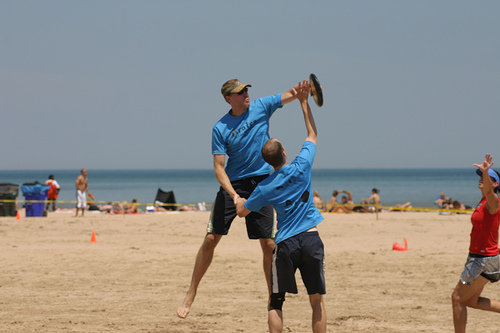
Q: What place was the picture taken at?
A: It was taken at the beach.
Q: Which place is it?
A: It is a beach.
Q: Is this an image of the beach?
A: Yes, it is showing the beach.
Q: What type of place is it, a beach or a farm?
A: It is a beach.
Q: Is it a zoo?
A: No, it is a beach.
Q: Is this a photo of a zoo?
A: No, the picture is showing a beach.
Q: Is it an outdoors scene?
A: Yes, it is outdoors.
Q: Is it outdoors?
A: Yes, it is outdoors.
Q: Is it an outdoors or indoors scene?
A: It is outdoors.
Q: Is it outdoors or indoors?
A: It is outdoors.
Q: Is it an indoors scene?
A: No, it is outdoors.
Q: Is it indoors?
A: No, it is outdoors.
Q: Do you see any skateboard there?
A: No, there are no skateboards.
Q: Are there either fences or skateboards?
A: No, there are no skateboards or fences.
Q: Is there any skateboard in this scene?
A: No, there are no skateboards.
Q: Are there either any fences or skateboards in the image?
A: No, there are no skateboards or fences.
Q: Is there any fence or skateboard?
A: No, there are no skateboards or fences.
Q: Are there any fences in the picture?
A: No, there are no fences.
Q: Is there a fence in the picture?
A: No, there are no fences.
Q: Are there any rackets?
A: No, there are no rackets.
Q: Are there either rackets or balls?
A: No, there are no rackets or balls.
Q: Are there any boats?
A: No, there are no boats.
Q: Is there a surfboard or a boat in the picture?
A: No, there are no boats or surfboards.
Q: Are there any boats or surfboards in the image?
A: No, there are no boats or surfboards.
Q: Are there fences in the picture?
A: No, there are no fences.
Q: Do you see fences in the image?
A: No, there are no fences.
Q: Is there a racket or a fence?
A: No, there are no fences or rackets.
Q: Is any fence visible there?
A: No, there are no fences.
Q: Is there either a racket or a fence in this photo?
A: No, there are no fences or rackets.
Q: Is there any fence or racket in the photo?
A: No, there are no fences or rackets.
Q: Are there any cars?
A: No, there are no cars.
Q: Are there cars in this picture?
A: No, there are no cars.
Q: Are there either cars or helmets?
A: No, there are no cars or helmets.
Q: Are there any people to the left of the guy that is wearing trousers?
A: Yes, there is a person to the left of the guy.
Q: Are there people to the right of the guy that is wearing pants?
A: No, the person is to the left of the guy.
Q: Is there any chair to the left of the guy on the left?
A: No, there is a person to the left of the guy.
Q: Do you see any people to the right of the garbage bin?
A: Yes, there is a person to the right of the garbage bin.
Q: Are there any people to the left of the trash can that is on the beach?
A: No, the person is to the right of the garbage bin.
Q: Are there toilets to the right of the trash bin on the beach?
A: No, there is a person to the right of the garbage can.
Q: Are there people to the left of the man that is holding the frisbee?
A: Yes, there is a person to the left of the man.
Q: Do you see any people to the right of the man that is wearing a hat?
A: No, the person is to the left of the man.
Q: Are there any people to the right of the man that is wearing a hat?
A: No, the person is to the left of the man.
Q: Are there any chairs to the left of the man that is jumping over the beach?
A: No, there is a person to the left of the man.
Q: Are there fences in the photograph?
A: No, there are no fences.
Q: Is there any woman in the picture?
A: Yes, there is a woman.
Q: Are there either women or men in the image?
A: Yes, there is a woman.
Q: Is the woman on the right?
A: Yes, the woman is on the right of the image.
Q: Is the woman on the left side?
A: No, the woman is on the right of the image.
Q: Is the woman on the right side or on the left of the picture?
A: The woman is on the right of the image.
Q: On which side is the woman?
A: The woman is on the right of the image.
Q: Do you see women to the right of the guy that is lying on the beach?
A: Yes, there is a woman to the right of the guy.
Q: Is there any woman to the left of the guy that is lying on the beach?
A: No, the woman is to the right of the guy.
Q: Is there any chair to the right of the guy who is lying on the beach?
A: No, there is a woman to the right of the guy.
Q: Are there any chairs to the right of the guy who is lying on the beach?
A: No, there is a woman to the right of the guy.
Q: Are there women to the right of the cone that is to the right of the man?
A: Yes, there is a woman to the right of the safety cone.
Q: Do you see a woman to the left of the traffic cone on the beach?
A: No, the woman is to the right of the traffic cone.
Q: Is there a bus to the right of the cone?
A: No, there is a woman to the right of the cone.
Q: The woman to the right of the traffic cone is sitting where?
A: The woman is sitting on the beach.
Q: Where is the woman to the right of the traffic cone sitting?
A: The woman is sitting on the beach.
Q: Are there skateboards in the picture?
A: No, there are no skateboards.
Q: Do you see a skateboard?
A: No, there are no skateboards.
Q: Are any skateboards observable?
A: No, there are no skateboards.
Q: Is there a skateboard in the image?
A: No, there are no skateboards.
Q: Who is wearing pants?
A: The guy is wearing pants.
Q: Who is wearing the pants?
A: The guy is wearing pants.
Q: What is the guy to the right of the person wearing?
A: The guy is wearing pants.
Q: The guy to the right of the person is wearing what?
A: The guy is wearing pants.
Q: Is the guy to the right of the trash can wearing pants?
A: Yes, the guy is wearing pants.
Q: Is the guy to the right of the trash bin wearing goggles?
A: No, the guy is wearing pants.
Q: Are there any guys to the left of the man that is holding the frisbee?
A: Yes, there is a guy to the left of the man.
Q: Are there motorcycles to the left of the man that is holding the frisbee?
A: No, there is a guy to the left of the man.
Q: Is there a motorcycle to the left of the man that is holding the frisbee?
A: No, there is a guy to the left of the man.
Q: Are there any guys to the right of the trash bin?
A: Yes, there is a guy to the right of the trash bin.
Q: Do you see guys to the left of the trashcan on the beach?
A: No, the guy is to the right of the garbage can.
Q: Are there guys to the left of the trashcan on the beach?
A: No, the guy is to the right of the garbage can.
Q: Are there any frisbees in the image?
A: Yes, there is a frisbee.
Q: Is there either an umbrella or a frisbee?
A: Yes, there is a frisbee.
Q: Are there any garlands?
A: No, there are no garlands.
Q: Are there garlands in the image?
A: No, there are no garlands.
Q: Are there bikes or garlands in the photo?
A: No, there are no garlands or bikes.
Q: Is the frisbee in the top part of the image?
A: Yes, the frisbee is in the top of the image.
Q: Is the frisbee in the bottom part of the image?
A: No, the frisbee is in the top of the image.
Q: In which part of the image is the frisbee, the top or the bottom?
A: The frisbee is in the top of the image.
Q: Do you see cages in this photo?
A: No, there are no cages.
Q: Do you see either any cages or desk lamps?
A: No, there are no cages or desk lamps.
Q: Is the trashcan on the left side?
A: Yes, the trashcan is on the left of the image.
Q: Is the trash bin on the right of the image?
A: No, the trash bin is on the left of the image.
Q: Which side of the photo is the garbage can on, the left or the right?
A: The garbage can is on the left of the image.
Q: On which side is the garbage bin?
A: The garbage bin is on the left of the image.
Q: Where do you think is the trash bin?
A: The trash bin is on the beach.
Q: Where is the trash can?
A: The trash bin is on the beach.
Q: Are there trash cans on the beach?
A: Yes, there is a trash can on the beach.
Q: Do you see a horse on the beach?
A: No, there is a trash can on the beach.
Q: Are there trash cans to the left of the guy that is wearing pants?
A: Yes, there is a trash can to the left of the guy.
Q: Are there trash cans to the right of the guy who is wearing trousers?
A: No, the trash can is to the left of the guy.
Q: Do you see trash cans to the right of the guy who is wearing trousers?
A: No, the trash can is to the left of the guy.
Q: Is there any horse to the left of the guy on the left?
A: No, there is a trash can to the left of the guy.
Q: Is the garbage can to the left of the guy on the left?
A: Yes, the garbage can is to the left of the guy.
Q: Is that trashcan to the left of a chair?
A: No, the trashcan is to the left of the guy.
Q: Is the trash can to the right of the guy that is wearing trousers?
A: No, the trash can is to the left of the guy.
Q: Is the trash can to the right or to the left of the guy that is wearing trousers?
A: The trash can is to the left of the guy.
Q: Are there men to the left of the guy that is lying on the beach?
A: Yes, there is a man to the left of the guy.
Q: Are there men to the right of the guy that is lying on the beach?
A: No, the man is to the left of the guy.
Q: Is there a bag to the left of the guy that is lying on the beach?
A: No, there is a man to the left of the guy.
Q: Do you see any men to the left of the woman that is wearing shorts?
A: Yes, there is a man to the left of the woman.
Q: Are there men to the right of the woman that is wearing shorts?
A: No, the man is to the left of the woman.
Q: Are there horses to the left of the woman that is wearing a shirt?
A: No, there is a man to the left of the woman.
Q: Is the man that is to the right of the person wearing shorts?
A: Yes, the man is wearing shorts.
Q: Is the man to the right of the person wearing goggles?
A: No, the man is wearing shorts.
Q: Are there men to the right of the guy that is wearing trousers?
A: Yes, there is a man to the right of the guy.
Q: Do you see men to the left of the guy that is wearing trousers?
A: No, the man is to the right of the guy.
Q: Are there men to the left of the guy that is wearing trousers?
A: No, the man is to the right of the guy.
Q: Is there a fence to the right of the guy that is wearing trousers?
A: No, there is a man to the right of the guy.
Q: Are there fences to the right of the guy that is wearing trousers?
A: No, there is a man to the right of the guy.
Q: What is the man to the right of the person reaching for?
A: The man is reaching for the frisbee.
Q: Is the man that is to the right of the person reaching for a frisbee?
A: Yes, the man is reaching for a frisbee.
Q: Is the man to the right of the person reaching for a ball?
A: No, the man is reaching for a frisbee.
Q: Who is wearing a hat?
A: The man is wearing a hat.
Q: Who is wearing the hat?
A: The man is wearing a hat.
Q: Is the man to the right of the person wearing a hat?
A: Yes, the man is wearing a hat.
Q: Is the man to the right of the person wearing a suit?
A: No, the man is wearing a hat.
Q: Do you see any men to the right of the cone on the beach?
A: No, the man is to the left of the safety cone.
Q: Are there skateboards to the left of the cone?
A: No, there is a man to the left of the cone.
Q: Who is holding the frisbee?
A: The man is holding the frisbee.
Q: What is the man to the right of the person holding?
A: The man is holding the frisbee.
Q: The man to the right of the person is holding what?
A: The man is holding the frisbee.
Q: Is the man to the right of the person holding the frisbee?
A: Yes, the man is holding the frisbee.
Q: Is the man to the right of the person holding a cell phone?
A: No, the man is holding the frisbee.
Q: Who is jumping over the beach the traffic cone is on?
A: The man is jumping over the beach.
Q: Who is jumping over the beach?
A: The man is jumping over the beach.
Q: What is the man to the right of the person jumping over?
A: The man is jumping over the beach.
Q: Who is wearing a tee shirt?
A: The man is wearing a tee shirt.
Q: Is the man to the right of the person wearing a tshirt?
A: Yes, the man is wearing a tshirt.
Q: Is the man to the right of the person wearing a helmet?
A: No, the man is wearing a tshirt.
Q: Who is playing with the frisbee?
A: The man is playing with the frisbee.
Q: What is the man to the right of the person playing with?
A: The man is playing with a frisbee.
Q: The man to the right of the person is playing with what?
A: The man is playing with a frisbee.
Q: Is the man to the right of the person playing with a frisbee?
A: Yes, the man is playing with a frisbee.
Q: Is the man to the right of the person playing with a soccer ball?
A: No, the man is playing with a frisbee.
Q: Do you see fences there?
A: No, there are no fences.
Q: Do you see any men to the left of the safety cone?
A: Yes, there is a man to the left of the safety cone.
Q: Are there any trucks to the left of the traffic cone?
A: No, there is a man to the left of the traffic cone.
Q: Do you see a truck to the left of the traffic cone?
A: No, there is a man to the left of the traffic cone.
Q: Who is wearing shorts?
A: The man is wearing shorts.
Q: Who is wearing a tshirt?
A: The man is wearing a tshirt.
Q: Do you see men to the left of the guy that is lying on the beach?
A: Yes, there is a man to the left of the guy.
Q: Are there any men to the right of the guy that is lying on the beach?
A: No, the man is to the left of the guy.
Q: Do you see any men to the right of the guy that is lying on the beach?
A: No, the man is to the left of the guy.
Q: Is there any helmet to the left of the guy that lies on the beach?
A: No, there is a man to the left of the guy.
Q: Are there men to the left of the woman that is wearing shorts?
A: Yes, there is a man to the left of the woman.